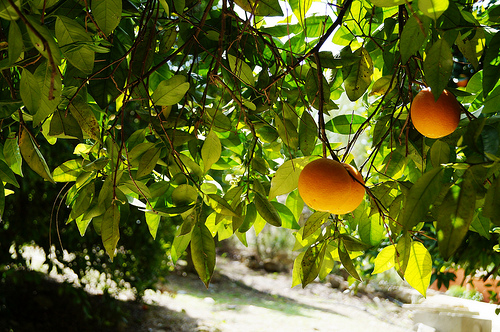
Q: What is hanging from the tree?
A: Oranges.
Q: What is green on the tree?
A: Leaves.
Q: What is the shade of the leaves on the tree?
A: Green.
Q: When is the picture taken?
A: Daytime.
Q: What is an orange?
A: A fruit.